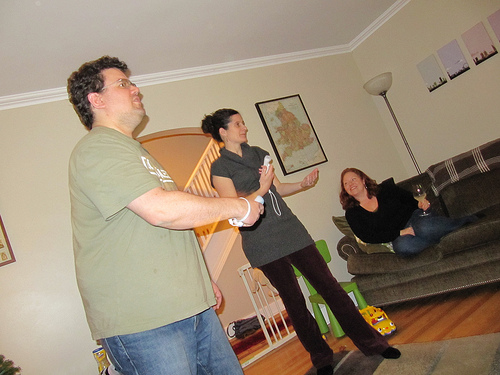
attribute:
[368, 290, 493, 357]
tiles — Wooden , floor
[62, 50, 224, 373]
person — in the picture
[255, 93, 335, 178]
frame — Photo 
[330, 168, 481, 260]
woman — in the picture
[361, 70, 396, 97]
lamp — night 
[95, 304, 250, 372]
jean — blue  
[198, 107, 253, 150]
woman's head — in the picture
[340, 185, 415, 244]
shirt — black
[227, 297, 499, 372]
floor — hardwood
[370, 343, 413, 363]
foot — in the picture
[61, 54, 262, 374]
man — in the picture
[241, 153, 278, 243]
controllers — white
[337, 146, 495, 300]
sofa — dark, colored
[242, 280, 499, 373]
floor — hardwood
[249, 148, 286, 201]
devices — electronic 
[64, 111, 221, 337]
t-shirt — round neck  , green  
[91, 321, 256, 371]
jeans — blue